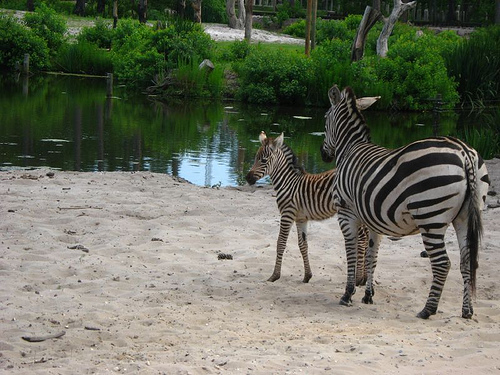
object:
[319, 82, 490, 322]
zebra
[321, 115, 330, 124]
eye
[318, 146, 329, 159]
nose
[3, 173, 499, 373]
ground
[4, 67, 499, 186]
water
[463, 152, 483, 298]
tail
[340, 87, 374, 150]
mane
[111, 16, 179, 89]
bush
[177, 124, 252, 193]
reflection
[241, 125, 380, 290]
baby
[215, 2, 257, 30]
tree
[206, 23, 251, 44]
sand